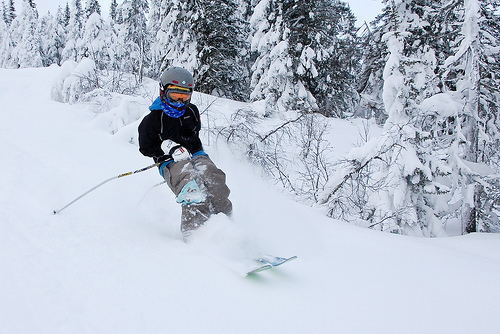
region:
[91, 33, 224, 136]
gray helmet on a skier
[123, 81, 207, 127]
blue bandanna on guy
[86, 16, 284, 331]
guy skiing down a hill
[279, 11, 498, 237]
snow covered trees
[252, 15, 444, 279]
trees on a hill covered in snow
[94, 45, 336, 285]
guy in snow on skis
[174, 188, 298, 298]
snow piled up on the skis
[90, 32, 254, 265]
guy in snow gear going down the hill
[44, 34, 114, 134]
snow piled up on bushes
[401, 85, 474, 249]
piles of snow on trees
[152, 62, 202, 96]
A grey ski helmet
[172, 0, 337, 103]
Snow covered pine trees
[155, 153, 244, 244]
Green snow pants covered with snow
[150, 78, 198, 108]
A fogged up ski mask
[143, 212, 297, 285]
A pair of skis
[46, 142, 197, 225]
A ski pole in action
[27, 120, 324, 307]
A snowy ski run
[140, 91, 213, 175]
A blue sweatshirt and hankerchief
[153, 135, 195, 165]
A white ski glove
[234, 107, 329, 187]
Small brush without leaves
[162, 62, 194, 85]
The gray helmet the skier is wearing.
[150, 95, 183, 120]
The blue scarf around the skier's neck.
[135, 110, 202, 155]
The black jacket the skier is wearing.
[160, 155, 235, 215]
The gray pants the skier is wearing.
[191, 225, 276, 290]
The skis the skier is wearing.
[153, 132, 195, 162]
The white glove the skier is wearing.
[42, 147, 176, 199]
The ski pole in the skier's hand.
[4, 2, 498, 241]
The snow covered trees in the background.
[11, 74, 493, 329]
The snow where the skier is skiing.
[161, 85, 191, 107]
The goggles the skier is wearing.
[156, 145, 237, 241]
THE SKIER IS WEARING PANTS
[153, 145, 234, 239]
THE SKIER'S PANTS ARE GREY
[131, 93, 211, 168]
THE SKIER IS WEARING A JACKET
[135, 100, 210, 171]
THE SKIER'S JACKET IS BLACK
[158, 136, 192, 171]
THE SKIER IS WEARING GLOVES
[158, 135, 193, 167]
THE SKIER'S GLOVES ARE WHITE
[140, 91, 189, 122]
THE SKIER IS WEARING A BANDANNA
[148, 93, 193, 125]
THE SKIER'S BANDANNA IS BLUE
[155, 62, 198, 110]
THE SKIER IS WEARING A HELMET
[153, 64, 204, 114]
THE SKIER'S HELMET IS GREY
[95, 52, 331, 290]
a kid snowboarding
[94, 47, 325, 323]
a kid on a snowboard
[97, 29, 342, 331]
a kid skiing in the snow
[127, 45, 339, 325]
a kid on skies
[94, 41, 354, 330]
a kid on the snow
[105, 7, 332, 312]
a kid leaning back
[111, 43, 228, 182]
a kid wearing a helmet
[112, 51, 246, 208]
a kid wearing a jacket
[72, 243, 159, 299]
snow covered ground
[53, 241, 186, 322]
ground covered in snow